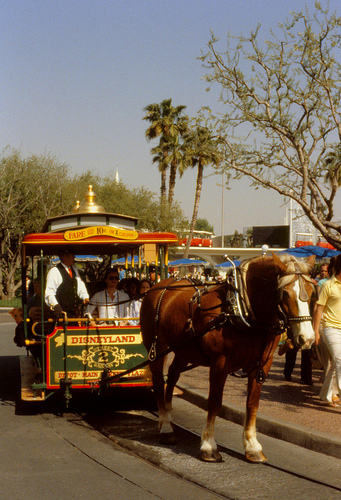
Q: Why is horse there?
A: Pulling trolley.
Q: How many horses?
A: One.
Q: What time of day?
A: Daytime.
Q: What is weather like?
A: Clear.